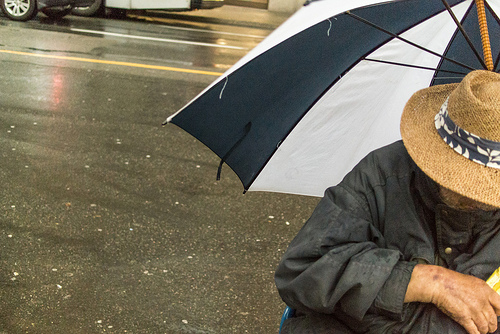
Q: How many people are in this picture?
A: 1.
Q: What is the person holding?
A: Umbrella.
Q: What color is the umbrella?
A: Blue and white.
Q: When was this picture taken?
A: Daytime.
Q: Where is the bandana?
A: Wrapped around hat.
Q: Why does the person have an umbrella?
A: It's raining.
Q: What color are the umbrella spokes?
A: Black.